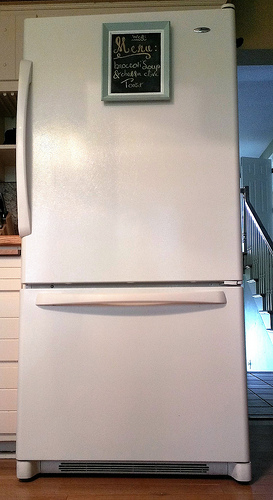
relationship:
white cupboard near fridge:
[1, 0, 222, 92] [15, 3, 250, 482]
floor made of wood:
[44, 477, 227, 499] [1, 481, 272, 495]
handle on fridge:
[14, 60, 37, 239] [21, 15, 242, 285]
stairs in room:
[241, 188, 272, 368] [235, 26, 271, 321]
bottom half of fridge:
[15, 287, 249, 464] [15, 3, 250, 482]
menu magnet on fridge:
[99, 21, 170, 102] [15, 3, 250, 482]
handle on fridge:
[14, 60, 37, 239] [15, 3, 250, 482]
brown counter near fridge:
[1, 233, 20, 243] [15, 3, 250, 482]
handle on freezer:
[27, 286, 227, 308] [12, 1, 255, 485]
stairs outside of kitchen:
[241, 188, 272, 338] [1, 1, 271, 498]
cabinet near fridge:
[1, 17, 27, 73] [25, 19, 228, 478]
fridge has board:
[40, 28, 258, 269] [100, 20, 173, 105]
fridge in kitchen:
[12, 0, 251, 484] [1, 1, 271, 498]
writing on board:
[108, 31, 158, 91] [103, 25, 169, 97]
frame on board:
[97, 19, 177, 105] [90, 12, 176, 106]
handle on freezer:
[29, 285, 235, 310] [35, 286, 237, 314]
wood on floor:
[0, 471, 242, 496] [3, 419, 271, 498]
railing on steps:
[240, 181, 271, 320] [236, 185, 264, 346]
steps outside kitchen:
[236, 185, 264, 346] [1, 1, 271, 498]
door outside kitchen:
[34, 62, 262, 270] [1, 1, 271, 498]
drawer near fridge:
[0, 259, 22, 289] [15, 3, 250, 482]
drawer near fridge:
[0, 299, 19, 362] [15, 3, 250, 482]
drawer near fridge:
[0, 368, 18, 434] [15, 3, 250, 482]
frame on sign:
[97, 19, 177, 105] [112, 35, 159, 91]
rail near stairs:
[240, 184, 272, 250] [245, 263, 271, 341]